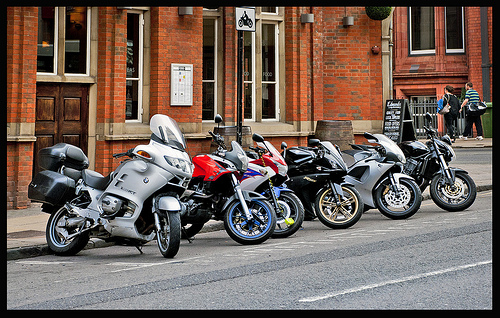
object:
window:
[261, 23, 276, 120]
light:
[164, 155, 195, 173]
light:
[237, 153, 249, 170]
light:
[392, 152, 406, 164]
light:
[329, 161, 336, 168]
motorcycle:
[27, 113, 194, 258]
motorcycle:
[181, 113, 277, 245]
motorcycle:
[211, 133, 304, 239]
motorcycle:
[279, 139, 363, 230]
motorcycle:
[341, 131, 421, 219]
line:
[298, 260, 493, 302]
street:
[5, 137, 491, 309]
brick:
[284, 7, 383, 121]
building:
[7, 6, 493, 210]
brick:
[148, 7, 202, 123]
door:
[32, 82, 88, 180]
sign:
[170, 63, 194, 106]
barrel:
[315, 120, 355, 151]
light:
[272, 160, 288, 177]